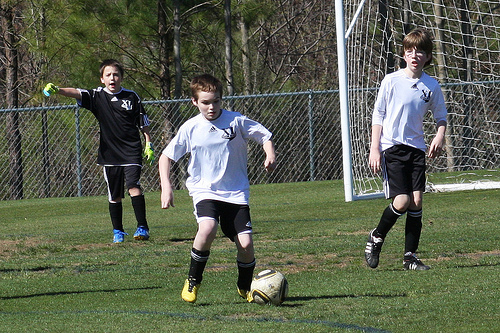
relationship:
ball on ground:
[245, 265, 289, 306] [28, 198, 495, 319]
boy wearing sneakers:
[168, 83, 286, 305] [177, 269, 282, 321]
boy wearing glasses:
[369, 37, 443, 285] [400, 39, 431, 63]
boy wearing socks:
[168, 83, 286, 305] [196, 240, 250, 292]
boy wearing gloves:
[48, 45, 191, 285] [38, 76, 68, 109]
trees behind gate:
[28, 2, 320, 97] [19, 97, 346, 190]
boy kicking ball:
[168, 83, 286, 305] [245, 265, 289, 306]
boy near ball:
[168, 83, 286, 305] [245, 265, 289, 306]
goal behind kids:
[337, 10, 499, 201] [65, 34, 455, 313]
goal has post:
[337, 10, 499, 201] [330, 7, 356, 214]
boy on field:
[168, 83, 286, 305] [28, 198, 495, 319]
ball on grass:
[245, 265, 289, 306] [126, 281, 391, 331]